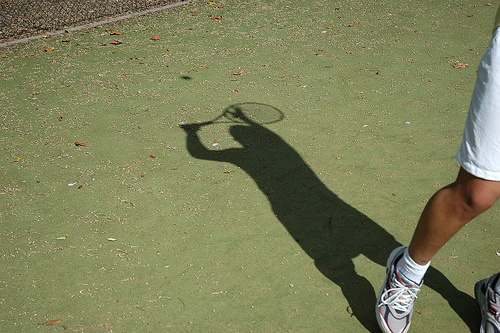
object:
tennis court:
[58, 75, 469, 274]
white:
[407, 263, 415, 278]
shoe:
[377, 246, 422, 332]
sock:
[396, 248, 431, 284]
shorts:
[466, 37, 496, 182]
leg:
[374, 78, 498, 330]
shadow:
[174, 90, 486, 332]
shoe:
[473, 273, 498, 331]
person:
[376, 7, 498, 329]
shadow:
[180, 72, 192, 79]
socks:
[396, 240, 498, 295]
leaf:
[71, 135, 90, 150]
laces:
[383, 264, 422, 319]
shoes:
[369, 235, 419, 331]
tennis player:
[375, 26, 498, 331]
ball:
[179, 64, 192, 86]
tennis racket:
[180, 100, 283, 132]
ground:
[0, 0, 499, 330]